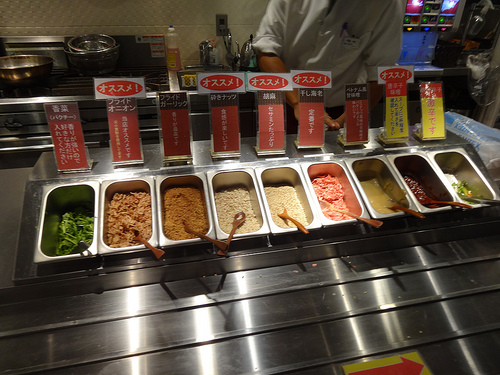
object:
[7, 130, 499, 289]
container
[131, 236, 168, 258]
handle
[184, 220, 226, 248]
handle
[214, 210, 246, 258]
handle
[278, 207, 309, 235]
handle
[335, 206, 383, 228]
handle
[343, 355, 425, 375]
arrow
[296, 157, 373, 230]
container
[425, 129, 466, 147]
ground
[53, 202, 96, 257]
condiment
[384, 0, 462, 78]
drink dispenser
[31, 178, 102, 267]
container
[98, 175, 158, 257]
container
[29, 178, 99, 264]
buffet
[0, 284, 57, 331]
bar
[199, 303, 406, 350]
surface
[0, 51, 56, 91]
pan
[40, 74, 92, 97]
cooker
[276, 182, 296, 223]
rice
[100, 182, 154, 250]
ocean water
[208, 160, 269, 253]
container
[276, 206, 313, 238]
stick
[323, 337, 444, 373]
counter arrow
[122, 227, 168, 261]
stick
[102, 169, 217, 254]
containers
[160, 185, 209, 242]
rice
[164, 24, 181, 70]
bottle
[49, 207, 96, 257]
vegetables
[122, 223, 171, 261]
spoons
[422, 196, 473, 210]
spoons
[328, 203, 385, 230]
spoons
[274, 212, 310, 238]
spoons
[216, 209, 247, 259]
spoons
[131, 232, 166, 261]
spoons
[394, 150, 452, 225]
container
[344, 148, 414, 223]
container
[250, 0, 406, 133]
man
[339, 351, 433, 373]
sticker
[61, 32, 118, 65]
metal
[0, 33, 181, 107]
stove top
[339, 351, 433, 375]
arrow sign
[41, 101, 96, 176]
sign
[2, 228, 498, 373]
counter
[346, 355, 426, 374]
red arrow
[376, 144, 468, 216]
metal container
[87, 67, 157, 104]
label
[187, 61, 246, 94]
label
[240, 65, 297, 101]
label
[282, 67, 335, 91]
label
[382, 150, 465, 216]
container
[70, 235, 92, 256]
spoon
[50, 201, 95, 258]
condiments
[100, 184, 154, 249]
condiments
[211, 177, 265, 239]
condiments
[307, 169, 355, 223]
condiments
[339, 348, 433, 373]
counter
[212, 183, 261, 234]
food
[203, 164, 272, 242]
container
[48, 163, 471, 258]
good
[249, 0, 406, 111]
shirt